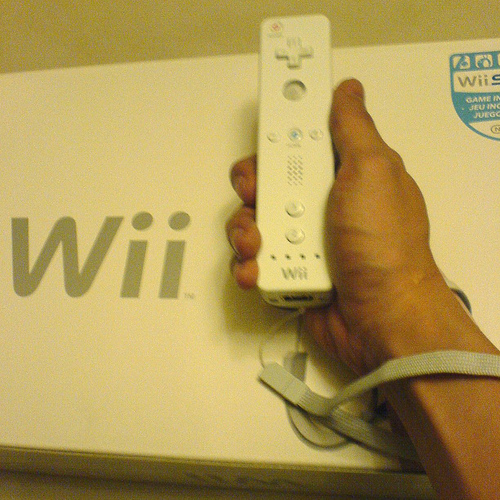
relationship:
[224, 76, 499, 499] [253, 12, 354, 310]
hand holding remote control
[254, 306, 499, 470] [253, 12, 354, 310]
strap on remote control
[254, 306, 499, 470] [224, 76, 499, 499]
strap around hand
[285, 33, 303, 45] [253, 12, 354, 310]
up button on remote control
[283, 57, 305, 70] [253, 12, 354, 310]
down button on remote control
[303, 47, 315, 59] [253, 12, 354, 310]
right button on remote control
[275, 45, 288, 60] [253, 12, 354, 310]
left button on remote control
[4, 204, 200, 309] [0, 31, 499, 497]
word on wii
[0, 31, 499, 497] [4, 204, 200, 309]
wii has word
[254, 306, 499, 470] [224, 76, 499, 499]
strap on hand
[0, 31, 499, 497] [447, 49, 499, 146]
wii has emblem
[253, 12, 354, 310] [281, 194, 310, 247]
remote control has buttons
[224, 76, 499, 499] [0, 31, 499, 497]
hand on wii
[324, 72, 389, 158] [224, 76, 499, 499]
thumb on hand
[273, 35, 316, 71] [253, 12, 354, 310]
d pad on remote control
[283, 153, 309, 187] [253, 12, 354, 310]
holes on remote control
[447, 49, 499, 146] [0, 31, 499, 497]
emblem on wii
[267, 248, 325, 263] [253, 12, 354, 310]
lights on remote control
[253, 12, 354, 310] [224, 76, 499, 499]
remote control in hand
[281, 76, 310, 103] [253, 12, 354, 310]
round button on remote control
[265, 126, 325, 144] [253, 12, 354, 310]
round buttons on remote control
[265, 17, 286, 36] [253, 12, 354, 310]
power button on remote control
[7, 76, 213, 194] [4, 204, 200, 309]
surface above word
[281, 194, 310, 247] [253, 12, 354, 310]
buttons on remote control